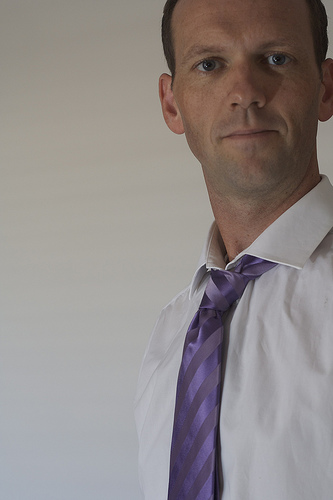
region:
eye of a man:
[181, 40, 235, 99]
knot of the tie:
[186, 260, 250, 324]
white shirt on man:
[242, 377, 310, 460]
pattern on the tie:
[172, 342, 214, 435]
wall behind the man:
[61, 169, 155, 256]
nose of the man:
[223, 69, 266, 119]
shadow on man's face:
[260, 67, 296, 106]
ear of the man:
[146, 60, 182, 146]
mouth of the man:
[213, 115, 288, 162]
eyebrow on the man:
[181, 36, 231, 62]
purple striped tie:
[164, 247, 252, 499]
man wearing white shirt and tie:
[132, 3, 331, 499]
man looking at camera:
[148, 4, 332, 232]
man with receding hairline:
[159, 1, 332, 204]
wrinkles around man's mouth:
[194, 84, 300, 169]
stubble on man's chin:
[184, 121, 330, 207]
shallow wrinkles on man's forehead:
[171, 1, 317, 44]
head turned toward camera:
[152, 0, 332, 266]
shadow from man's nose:
[210, 14, 325, 154]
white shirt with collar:
[138, 171, 332, 491]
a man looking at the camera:
[127, 0, 331, 170]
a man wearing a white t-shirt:
[136, 39, 331, 497]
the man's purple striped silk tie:
[157, 240, 293, 492]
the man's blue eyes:
[185, 42, 302, 76]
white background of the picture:
[14, 361, 108, 462]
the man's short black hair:
[138, 0, 188, 77]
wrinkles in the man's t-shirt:
[239, 282, 320, 388]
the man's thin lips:
[216, 120, 282, 148]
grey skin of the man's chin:
[192, 140, 300, 194]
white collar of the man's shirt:
[182, 177, 323, 291]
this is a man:
[140, 11, 331, 280]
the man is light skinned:
[219, 91, 248, 158]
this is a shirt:
[245, 305, 295, 408]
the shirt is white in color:
[242, 375, 299, 486]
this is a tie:
[178, 318, 203, 404]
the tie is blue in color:
[184, 362, 211, 410]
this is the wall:
[36, 54, 130, 363]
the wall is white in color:
[47, 226, 99, 294]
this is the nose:
[227, 86, 274, 108]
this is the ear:
[154, 76, 178, 111]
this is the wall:
[11, 184, 96, 253]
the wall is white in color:
[11, 396, 99, 474]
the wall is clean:
[8, 396, 87, 460]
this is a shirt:
[231, 390, 331, 489]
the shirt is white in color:
[233, 412, 278, 454]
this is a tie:
[187, 280, 224, 437]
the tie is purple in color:
[186, 337, 209, 443]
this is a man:
[151, 4, 327, 324]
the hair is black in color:
[159, 36, 168, 49]